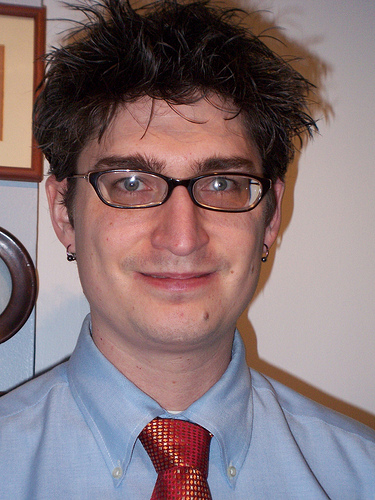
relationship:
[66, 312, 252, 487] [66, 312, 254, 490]
part of collar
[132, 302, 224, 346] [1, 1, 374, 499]
chin of man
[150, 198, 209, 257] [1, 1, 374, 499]
nose of man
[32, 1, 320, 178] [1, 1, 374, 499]
hair of man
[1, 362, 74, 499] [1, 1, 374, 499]
shoulder of man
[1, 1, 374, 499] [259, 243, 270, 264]
man's black earring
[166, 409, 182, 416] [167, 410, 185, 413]
white tee shirt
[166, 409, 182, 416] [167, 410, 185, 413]
white of shirt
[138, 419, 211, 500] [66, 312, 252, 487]
tie around neck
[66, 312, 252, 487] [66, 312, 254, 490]
blue shirt collar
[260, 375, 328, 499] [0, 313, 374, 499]
crease in shirt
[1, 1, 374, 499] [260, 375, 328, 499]
man's shirt crease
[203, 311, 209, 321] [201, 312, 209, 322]
mole black mole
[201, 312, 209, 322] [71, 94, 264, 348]
mole on face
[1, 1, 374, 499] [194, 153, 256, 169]
man's bushy bushy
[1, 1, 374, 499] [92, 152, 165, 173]
man's bushy brow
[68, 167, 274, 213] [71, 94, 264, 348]
glasses on face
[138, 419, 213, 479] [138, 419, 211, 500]
red knotted tie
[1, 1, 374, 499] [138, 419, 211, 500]
man's knotted tie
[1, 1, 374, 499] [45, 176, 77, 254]
man's right ear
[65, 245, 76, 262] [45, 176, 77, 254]
earring in ear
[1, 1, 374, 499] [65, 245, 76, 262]
man's right earring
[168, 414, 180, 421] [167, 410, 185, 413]
button down shirt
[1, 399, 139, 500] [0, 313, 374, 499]
blue button shirt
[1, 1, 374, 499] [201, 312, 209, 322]
man's chin pimple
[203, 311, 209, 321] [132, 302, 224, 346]
mole on chin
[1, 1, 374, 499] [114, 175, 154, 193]
man has eye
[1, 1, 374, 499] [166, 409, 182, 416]
man's white t-shirt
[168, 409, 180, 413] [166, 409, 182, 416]
sliver of t-shirt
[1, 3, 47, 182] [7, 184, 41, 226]
picture on wall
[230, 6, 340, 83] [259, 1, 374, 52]
shadow on wall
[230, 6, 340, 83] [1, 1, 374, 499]
shadow behind man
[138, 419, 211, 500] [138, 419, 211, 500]
part of tie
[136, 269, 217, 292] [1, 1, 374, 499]
mouth of man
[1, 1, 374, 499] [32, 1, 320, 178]
man mans hair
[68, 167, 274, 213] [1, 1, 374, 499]
glasses of man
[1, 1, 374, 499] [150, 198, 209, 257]
man mans nose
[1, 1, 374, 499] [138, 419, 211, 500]
man wearing tie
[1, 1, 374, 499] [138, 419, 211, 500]
man red tie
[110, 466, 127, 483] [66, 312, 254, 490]
button holding collar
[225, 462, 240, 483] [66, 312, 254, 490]
button holding collar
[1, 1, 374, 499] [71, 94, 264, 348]
man's shaved face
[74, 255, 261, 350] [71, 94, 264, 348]
shaved mans face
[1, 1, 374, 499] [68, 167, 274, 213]
man wearing glasses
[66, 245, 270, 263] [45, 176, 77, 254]
man's pierced ear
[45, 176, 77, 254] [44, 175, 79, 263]
man's pierced ear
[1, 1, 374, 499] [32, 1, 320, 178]
man's brown hair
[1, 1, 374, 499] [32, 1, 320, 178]
man's dark hair